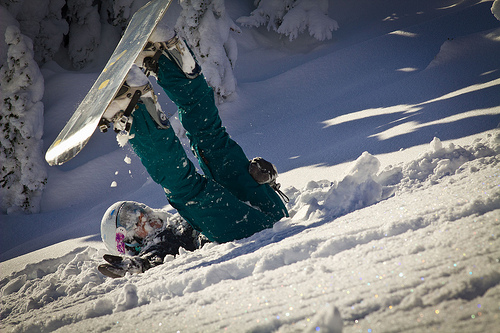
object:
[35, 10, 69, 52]
tree branch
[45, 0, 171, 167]
bottom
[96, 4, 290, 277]
boarder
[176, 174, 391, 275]
shadow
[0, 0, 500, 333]
snow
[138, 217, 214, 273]
coat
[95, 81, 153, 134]
boots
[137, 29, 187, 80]
boots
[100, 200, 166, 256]
helmet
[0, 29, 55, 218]
tree branch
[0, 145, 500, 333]
field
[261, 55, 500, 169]
shadow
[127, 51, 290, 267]
suit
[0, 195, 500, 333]
tracks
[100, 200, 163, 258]
head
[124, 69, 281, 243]
legs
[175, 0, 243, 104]
branch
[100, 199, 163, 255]
hat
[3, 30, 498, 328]
ground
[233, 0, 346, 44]
tree branch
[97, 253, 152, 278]
black mitten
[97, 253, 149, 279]
hand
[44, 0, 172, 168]
board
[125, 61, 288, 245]
pants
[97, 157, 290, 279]
gloves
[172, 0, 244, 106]
tree branch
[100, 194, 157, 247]
googles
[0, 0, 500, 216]
trees